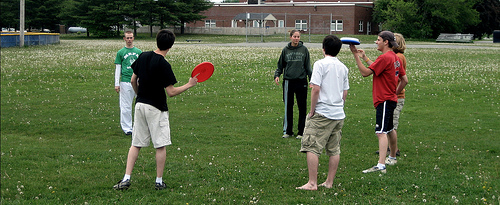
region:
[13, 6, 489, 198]
college kids are playing frisbee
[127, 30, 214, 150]
the boy is about to throw a red frisbee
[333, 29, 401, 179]
the boy has a blue and white frisbee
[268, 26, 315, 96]
the girl has a sweatshirt hoodie on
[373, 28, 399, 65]
the boy has a cap on backwards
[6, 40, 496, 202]
white flowers are blooming in the field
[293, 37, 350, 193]
the boy is barefoot on the field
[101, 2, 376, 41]
a red brick building is behind the field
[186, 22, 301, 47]
a white fence is in front of the building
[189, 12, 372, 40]
windows are on the building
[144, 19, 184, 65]
the head of a man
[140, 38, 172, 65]
the neck of a man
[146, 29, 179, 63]
the hair of a man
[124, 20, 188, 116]
the back of a man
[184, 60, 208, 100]
the hand of a man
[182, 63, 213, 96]
the finger of a man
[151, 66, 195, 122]
the arm of a man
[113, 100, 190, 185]
the legs of a man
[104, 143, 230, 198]
the foot of a man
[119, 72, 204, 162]
a man wearing shorts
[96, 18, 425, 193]
a group of people standing in a circle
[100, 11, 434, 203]
six people standing in the grass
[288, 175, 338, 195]
no shoes on the feet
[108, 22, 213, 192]
man holding a red frisbee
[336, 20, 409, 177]
man holding a blue frisbee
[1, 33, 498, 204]
green grass on the ground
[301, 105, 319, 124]
hand on the hip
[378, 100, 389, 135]
white stripe on the side of the shorts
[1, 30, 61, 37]
yellow stripe at the top of the fence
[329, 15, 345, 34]
window on the side of the building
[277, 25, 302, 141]
girl wearing green and black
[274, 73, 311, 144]
girl wearing black pants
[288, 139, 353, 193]
guy is in barefeet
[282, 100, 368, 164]
guy is wearing shorts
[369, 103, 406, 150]
guy is wearing black shorts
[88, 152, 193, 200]
man is wearing white socks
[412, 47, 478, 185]
large green grass field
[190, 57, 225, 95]
man is holding frisbee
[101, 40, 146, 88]
man is wearing green shirt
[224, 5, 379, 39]
large building in background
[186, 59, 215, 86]
Red frisbee in man's hand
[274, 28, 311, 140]
Woman in field wearing hoodie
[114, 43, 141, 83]
Men's short sleeved green shirt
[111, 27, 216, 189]
Man in black shirt holding frisbee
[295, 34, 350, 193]
Man in white shirt with hands in pockets of shorts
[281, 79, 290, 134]
White stripe on woman's sweatpants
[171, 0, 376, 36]
Brick building in the background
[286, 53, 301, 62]
Logo on the front of woman's hoodie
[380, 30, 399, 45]
Black cap on man's head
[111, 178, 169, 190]
Gray and black shoes on man's feet